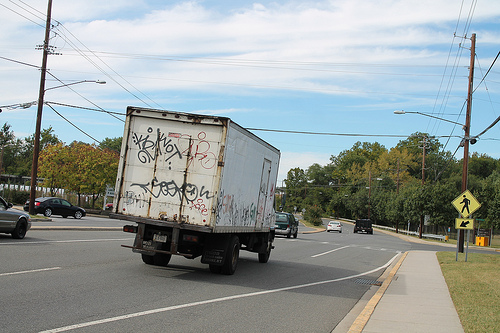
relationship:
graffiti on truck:
[126, 124, 211, 208] [116, 103, 282, 274]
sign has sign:
[453, 218, 476, 231] [453, 218, 476, 231]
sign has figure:
[452, 189, 483, 219] [458, 194, 473, 215]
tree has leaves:
[70, 144, 112, 180] [75, 149, 83, 156]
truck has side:
[116, 103, 282, 274] [226, 126, 279, 228]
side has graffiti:
[226, 126, 279, 228] [221, 194, 258, 224]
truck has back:
[116, 103, 282, 274] [127, 117, 215, 223]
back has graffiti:
[127, 117, 215, 223] [126, 124, 211, 208]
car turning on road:
[28, 190, 88, 216] [87, 215, 109, 224]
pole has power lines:
[463, 30, 472, 188] [290, 127, 388, 140]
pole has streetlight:
[463, 30, 472, 188] [393, 105, 408, 120]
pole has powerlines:
[36, 73, 48, 176] [62, 103, 113, 115]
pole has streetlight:
[36, 73, 48, 176] [75, 78, 116, 84]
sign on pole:
[453, 218, 476, 231] [463, 30, 472, 188]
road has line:
[87, 215, 109, 224] [317, 239, 354, 265]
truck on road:
[116, 103, 282, 274] [87, 215, 109, 224]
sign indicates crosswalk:
[452, 189, 483, 219] [317, 237, 400, 256]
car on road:
[326, 218, 345, 234] [87, 215, 109, 224]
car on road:
[353, 215, 375, 236] [87, 215, 109, 224]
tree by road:
[70, 144, 112, 180] [0, 216, 497, 332]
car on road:
[28, 190, 88, 216] [0, 216, 497, 332]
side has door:
[226, 126, 279, 228] [259, 157, 274, 230]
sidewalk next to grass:
[402, 250, 441, 312] [462, 272, 490, 307]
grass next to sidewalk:
[462, 272, 490, 307] [402, 250, 441, 312]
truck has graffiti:
[116, 103, 282, 274] [126, 124, 211, 208]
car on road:
[28, 190, 88, 216] [87, 215, 109, 224]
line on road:
[317, 239, 354, 265] [87, 215, 109, 224]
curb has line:
[385, 255, 408, 283] [385, 265, 398, 280]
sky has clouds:
[267, 97, 324, 116] [279, 21, 316, 47]